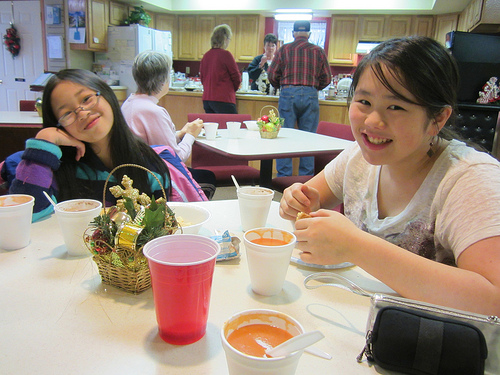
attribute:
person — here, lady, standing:
[201, 23, 242, 113]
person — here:
[249, 34, 278, 96]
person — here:
[268, 24, 331, 178]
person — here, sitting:
[121, 51, 217, 200]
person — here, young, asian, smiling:
[279, 36, 499, 318]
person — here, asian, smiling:
[8, 70, 170, 223]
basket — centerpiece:
[92, 163, 178, 292]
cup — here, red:
[143, 236, 221, 344]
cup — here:
[246, 227, 295, 296]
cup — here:
[1, 195, 35, 250]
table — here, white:
[185, 125, 355, 160]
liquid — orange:
[226, 325, 294, 357]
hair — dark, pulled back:
[348, 37, 499, 156]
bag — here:
[306, 272, 499, 374]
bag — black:
[359, 307, 487, 373]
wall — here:
[172, 12, 367, 94]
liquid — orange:
[252, 239, 288, 246]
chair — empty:
[188, 113, 260, 186]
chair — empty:
[274, 121, 356, 188]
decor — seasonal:
[6, 26, 20, 57]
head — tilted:
[50, 78, 115, 142]